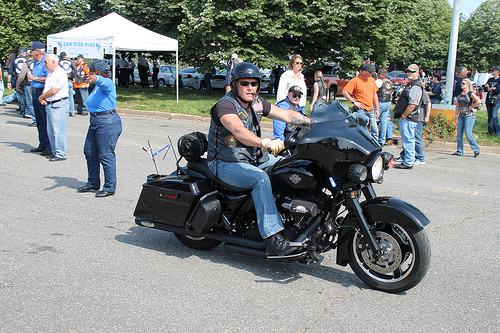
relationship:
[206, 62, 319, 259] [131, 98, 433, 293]
man on motorcycle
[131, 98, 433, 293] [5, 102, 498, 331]
motorcycle on road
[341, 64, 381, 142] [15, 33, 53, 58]
man in hat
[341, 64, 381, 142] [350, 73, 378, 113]
man in shirt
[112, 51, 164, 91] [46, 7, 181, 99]
group standing under canopy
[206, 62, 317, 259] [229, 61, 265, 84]
man wearing helmet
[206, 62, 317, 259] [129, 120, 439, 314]
man riding motorcycle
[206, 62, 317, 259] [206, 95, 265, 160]
man wearing vest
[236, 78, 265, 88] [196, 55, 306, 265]
sunglasses on man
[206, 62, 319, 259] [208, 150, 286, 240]
man wearing jeans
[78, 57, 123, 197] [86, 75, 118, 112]
person wearing shirt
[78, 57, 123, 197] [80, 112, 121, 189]
person wearing blue jeans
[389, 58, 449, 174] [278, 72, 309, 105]
person wearing shirt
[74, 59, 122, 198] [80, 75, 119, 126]
person wearing shirt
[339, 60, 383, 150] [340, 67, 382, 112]
man wearing shirt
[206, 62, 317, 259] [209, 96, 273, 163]
man wearing vest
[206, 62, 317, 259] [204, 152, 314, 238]
man wears jeans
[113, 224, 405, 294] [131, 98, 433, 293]
shadow of motorcycle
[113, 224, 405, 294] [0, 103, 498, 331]
shadow on pavement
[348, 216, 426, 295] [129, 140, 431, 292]
wheel on motorcycle